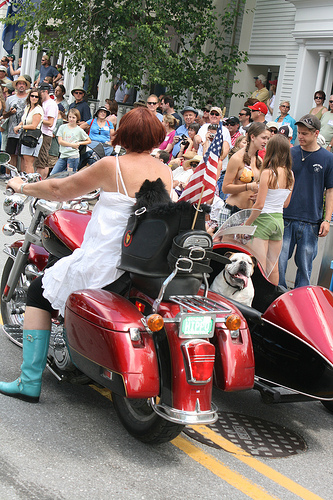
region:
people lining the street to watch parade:
[5, 49, 329, 286]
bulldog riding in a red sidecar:
[187, 238, 329, 394]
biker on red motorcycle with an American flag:
[8, 87, 224, 443]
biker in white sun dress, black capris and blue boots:
[4, 105, 176, 403]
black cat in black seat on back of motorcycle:
[115, 173, 212, 370]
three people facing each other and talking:
[237, 116, 329, 190]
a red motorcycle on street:
[2, 198, 255, 442]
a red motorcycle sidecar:
[207, 205, 330, 410]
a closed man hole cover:
[187, 408, 306, 458]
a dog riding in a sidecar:
[200, 207, 330, 400]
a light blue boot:
[0, 330, 52, 400]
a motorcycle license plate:
[179, 315, 213, 336]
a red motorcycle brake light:
[188, 338, 216, 383]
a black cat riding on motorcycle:
[131, 177, 171, 218]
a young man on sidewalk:
[279, 113, 332, 289]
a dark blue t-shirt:
[282, 144, 331, 224]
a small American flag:
[179, 123, 223, 201]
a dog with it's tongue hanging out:
[210, 250, 255, 306]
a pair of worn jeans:
[277, 219, 317, 291]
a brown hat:
[294, 114, 320, 132]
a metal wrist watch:
[321, 217, 331, 221]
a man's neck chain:
[298, 140, 318, 160]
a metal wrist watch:
[17, 181, 26, 193]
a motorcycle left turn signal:
[146, 313, 164, 332]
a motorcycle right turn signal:
[224, 313, 241, 331]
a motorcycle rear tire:
[108, 391, 183, 446]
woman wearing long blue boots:
[2, 328, 53, 402]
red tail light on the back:
[191, 340, 212, 385]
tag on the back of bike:
[180, 316, 213, 338]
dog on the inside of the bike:
[227, 250, 261, 299]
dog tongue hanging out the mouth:
[240, 273, 245, 286]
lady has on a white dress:
[79, 222, 113, 273]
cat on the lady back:
[136, 178, 162, 207]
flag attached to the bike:
[190, 122, 221, 208]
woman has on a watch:
[19, 177, 27, 194]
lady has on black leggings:
[30, 286, 36, 304]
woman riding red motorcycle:
[4, 102, 332, 450]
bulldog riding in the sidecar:
[213, 253, 259, 307]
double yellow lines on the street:
[93, 371, 329, 498]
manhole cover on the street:
[182, 405, 297, 467]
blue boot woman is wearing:
[1, 328, 49, 404]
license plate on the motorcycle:
[178, 314, 213, 338]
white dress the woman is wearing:
[47, 163, 155, 305]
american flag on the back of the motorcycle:
[175, 123, 231, 230]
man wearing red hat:
[245, 102, 268, 124]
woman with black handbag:
[13, 89, 46, 164]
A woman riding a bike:
[56, 101, 177, 316]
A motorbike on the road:
[82, 267, 249, 426]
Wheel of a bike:
[112, 397, 189, 449]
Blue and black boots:
[0, 325, 55, 411]